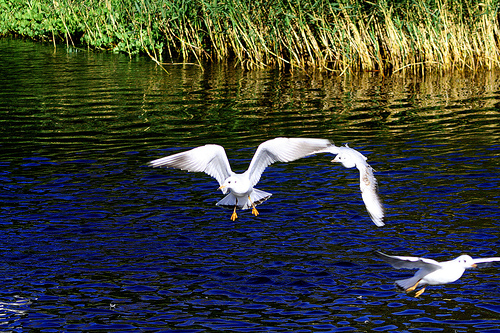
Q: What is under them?
A: Water.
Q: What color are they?
A: White.